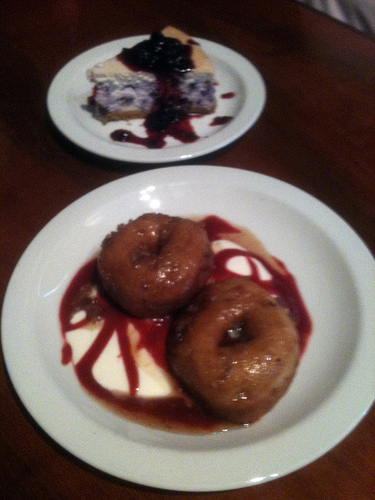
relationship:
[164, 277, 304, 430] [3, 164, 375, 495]
doughnuts on plate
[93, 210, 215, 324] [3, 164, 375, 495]
doughnuts on plate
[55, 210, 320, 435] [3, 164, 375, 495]
sauce on plate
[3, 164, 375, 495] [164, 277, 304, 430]
plate with doughnuts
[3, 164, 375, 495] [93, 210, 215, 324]
plate with doughnuts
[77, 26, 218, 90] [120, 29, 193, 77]
dessert with sauce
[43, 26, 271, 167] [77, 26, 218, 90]
plate with dessert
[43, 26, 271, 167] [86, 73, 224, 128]
plate with food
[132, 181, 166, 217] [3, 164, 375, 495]
reflection on plate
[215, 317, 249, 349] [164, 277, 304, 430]
hole in doughnuts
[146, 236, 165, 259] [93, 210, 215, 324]
hole in doughnuts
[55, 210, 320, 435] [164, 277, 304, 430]
sauce over doughnuts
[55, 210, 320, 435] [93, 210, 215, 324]
sauce over doughnuts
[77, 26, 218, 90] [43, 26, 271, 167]
dessert on plate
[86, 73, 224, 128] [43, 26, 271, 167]
food on plate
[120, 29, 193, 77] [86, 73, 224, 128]
sauce on food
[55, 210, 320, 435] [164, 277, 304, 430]
sauce under doughnuts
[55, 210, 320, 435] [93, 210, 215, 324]
sauce under doughnuts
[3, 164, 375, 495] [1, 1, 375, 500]
plate on table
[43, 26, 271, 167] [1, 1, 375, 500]
plate on table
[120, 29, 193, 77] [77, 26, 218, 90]
sauce on dessert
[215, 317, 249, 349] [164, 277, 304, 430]
hole of doughnuts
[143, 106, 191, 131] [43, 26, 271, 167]
fruit on plate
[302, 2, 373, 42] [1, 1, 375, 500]
someone by table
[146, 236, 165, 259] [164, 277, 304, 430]
hole of doughnuts